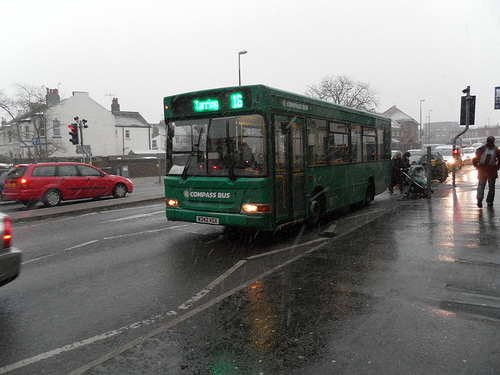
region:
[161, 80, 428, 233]
green Compass bus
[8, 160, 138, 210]
red station wagon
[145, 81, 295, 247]
bus driving route 16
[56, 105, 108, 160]
stoplight with red light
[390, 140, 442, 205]
two people pushing a stroller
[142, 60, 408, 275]
bus driving in the rain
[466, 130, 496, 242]
man walking in the rain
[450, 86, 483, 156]
back of a stoplight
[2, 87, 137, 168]
white townhouses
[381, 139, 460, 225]
people getting off a bus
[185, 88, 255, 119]
Bright green bus sign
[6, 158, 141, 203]
Bright red car with lights on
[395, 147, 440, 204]
Person with a baby stroller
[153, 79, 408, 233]
Large dark green bus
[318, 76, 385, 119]
Top of a tree in background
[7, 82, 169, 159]
Two story white buildings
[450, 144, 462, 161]
Small red light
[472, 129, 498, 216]
Person walking in the rain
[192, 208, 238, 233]
Black and white license plate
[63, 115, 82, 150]
Red traffic light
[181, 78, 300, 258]
A green bus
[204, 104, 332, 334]
A green bus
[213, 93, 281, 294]
A green bus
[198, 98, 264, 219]
A green bus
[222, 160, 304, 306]
A green bus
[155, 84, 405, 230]
a green bus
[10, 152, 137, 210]
a red station wagon on a road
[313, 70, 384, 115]
a bare leafless tree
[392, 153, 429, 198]
a stroller being pushed across a road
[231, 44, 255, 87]
a light pole behind a bus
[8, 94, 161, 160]
a white building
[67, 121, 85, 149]
a red stoplight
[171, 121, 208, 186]
a windshield wiper on a bus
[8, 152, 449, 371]
a wet slick winter road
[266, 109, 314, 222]
the door on a bus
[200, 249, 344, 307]
triangular line on road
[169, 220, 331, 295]
rain falling on the road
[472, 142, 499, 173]
black and white back pack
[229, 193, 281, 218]
bright light on front of green bus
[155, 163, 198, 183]
white sign in front of bus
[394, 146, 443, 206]
woman pushing baby carraige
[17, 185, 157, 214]
island barrier in street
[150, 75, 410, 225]
green bus in street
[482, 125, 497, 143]
cap on man's head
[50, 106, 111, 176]
red light on traffic signal